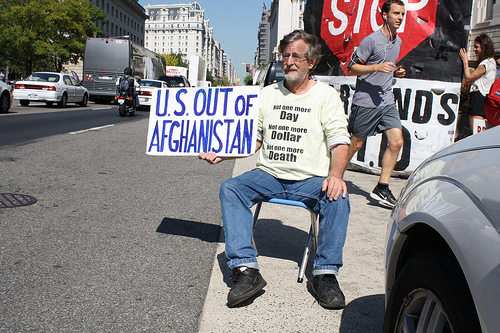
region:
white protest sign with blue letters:
[145, 82, 265, 161]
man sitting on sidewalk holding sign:
[145, 25, 360, 307]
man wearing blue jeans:
[201, 20, 366, 306]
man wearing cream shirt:
[191, 25, 366, 307]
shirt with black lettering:
[227, 71, 348, 176]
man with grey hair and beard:
[196, 25, 374, 310]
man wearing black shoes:
[205, 24, 369, 316]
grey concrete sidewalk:
[203, 142, 430, 329]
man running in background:
[343, 0, 411, 210]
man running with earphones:
[331, 0, 418, 212]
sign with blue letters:
[142, 76, 269, 161]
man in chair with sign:
[138, 21, 363, 311]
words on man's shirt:
[259, 99, 323, 170]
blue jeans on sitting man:
[206, 158, 358, 283]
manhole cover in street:
[1, 173, 40, 222]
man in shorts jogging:
[313, 3, 413, 217]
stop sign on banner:
[310, 3, 447, 82]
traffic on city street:
[9, 33, 213, 118]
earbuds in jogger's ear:
[373, 13, 395, 75]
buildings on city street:
[101, 0, 234, 81]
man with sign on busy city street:
[141, 27, 358, 309]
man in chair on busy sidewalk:
[225, 22, 349, 316]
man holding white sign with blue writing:
[146, 33, 348, 170]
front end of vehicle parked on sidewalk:
[235, 129, 495, 322]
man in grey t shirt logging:
[344, 1, 416, 222]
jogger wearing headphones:
[357, 2, 404, 99]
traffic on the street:
[8, 14, 176, 157]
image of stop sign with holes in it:
[289, 0, 438, 82]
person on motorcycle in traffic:
[105, 61, 142, 141]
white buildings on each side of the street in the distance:
[44, 3, 276, 79]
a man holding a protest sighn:
[102, 17, 361, 317]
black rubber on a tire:
[413, 259, 458, 293]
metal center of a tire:
[404, 302, 437, 324]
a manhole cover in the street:
[5, 185, 44, 211]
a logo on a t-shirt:
[261, 103, 316, 170]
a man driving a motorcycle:
[111, 68, 142, 124]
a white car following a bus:
[11, 66, 103, 116]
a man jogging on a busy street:
[352, 0, 413, 193]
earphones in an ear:
[379, 10, 392, 30]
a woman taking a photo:
[447, 26, 494, 123]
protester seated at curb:
[88, 30, 365, 315]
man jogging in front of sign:
[340, 0, 415, 220]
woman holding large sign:
[417, 15, 492, 126]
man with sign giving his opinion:
[135, 25, 350, 205]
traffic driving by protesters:
[5, 10, 350, 221]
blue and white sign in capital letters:
[122, 82, 272, 162]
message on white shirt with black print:
[240, 45, 367, 190]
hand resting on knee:
[285, 92, 360, 257]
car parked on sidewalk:
[332, 115, 492, 320]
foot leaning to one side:
[193, 235, 280, 315]